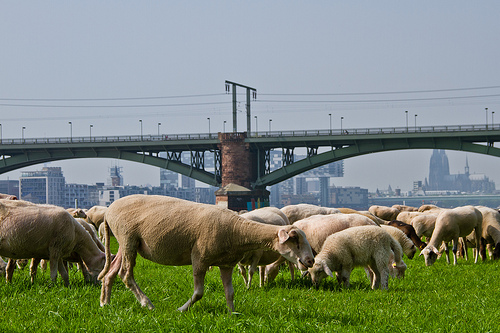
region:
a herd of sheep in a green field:
[2, 185, 499, 324]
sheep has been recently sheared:
[91, 192, 319, 318]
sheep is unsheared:
[306, 223, 405, 298]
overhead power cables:
[1, 83, 498, 109]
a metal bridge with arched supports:
[0, 108, 499, 202]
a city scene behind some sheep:
[4, 143, 498, 325]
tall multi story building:
[12, 170, 67, 207]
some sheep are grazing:
[3, 188, 498, 320]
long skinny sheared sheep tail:
[95, 211, 115, 286]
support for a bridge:
[215, 125, 258, 207]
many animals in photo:
[8, 174, 476, 307]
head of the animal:
[257, 212, 328, 279]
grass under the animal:
[267, 287, 348, 332]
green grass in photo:
[270, 286, 360, 323]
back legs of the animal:
[81, 234, 161, 316]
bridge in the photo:
[27, 85, 475, 193]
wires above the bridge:
[292, 69, 415, 119]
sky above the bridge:
[246, 8, 375, 51]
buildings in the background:
[377, 139, 485, 199]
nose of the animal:
[300, 249, 323, 274]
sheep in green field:
[2, 184, 497, 331]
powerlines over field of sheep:
[3, 78, 498, 110]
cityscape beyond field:
[6, 139, 498, 199]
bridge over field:
[2, 111, 498, 173]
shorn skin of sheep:
[135, 202, 182, 242]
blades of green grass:
[271, 292, 318, 314]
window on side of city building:
[65, 186, 82, 198]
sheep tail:
[95, 216, 119, 283]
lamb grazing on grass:
[299, 221, 411, 291]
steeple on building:
[459, 151, 473, 168]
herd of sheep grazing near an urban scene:
[2, 93, 494, 331]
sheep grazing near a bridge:
[3, 45, 490, 329]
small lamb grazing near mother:
[280, 213, 403, 297]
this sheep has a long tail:
[97, 209, 112, 289]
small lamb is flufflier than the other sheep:
[310, 230, 405, 299]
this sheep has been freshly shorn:
[96, 190, 310, 322]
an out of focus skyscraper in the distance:
[415, 145, 463, 197]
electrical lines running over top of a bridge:
[220, 73, 373, 110]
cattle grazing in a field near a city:
[6, 21, 496, 318]